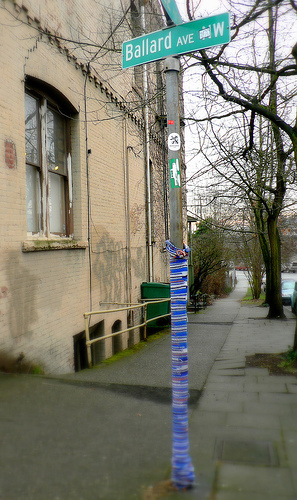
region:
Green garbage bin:
[141, 280, 169, 330]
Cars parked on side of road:
[282, 276, 295, 314]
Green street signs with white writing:
[120, 0, 232, 70]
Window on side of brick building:
[25, 72, 78, 245]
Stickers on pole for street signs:
[165, 119, 181, 192]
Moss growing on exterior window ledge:
[31, 237, 78, 247]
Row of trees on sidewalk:
[232, 108, 289, 322]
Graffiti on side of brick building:
[93, 231, 147, 303]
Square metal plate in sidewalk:
[213, 433, 280, 469]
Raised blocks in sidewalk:
[213, 355, 246, 380]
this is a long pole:
[163, 312, 219, 374]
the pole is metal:
[155, 208, 209, 312]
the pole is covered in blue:
[115, 288, 182, 356]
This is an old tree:
[218, 222, 280, 273]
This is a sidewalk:
[214, 322, 219, 417]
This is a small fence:
[71, 272, 163, 381]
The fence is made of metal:
[109, 310, 147, 403]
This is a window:
[26, 209, 49, 217]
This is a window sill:
[35, 212, 63, 238]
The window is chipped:
[37, 201, 61, 244]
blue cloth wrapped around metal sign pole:
[164, 238, 199, 489]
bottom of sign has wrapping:
[164, 235, 199, 483]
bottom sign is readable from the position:
[121, 11, 232, 67]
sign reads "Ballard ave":
[117, 9, 233, 62]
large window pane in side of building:
[22, 71, 81, 245]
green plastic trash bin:
[141, 280, 170, 330]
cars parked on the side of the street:
[277, 275, 296, 312]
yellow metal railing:
[74, 293, 179, 365]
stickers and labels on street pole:
[165, 116, 187, 195]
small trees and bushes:
[187, 214, 231, 312]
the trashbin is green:
[139, 272, 180, 333]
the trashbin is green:
[122, 268, 193, 353]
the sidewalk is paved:
[181, 287, 253, 405]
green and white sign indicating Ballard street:
[119, 12, 232, 68]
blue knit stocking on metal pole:
[164, 238, 199, 486]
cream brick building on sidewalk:
[0, 0, 190, 373]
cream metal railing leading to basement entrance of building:
[78, 290, 171, 359]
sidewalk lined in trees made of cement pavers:
[169, 284, 292, 486]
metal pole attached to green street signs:
[161, 55, 182, 246]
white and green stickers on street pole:
[169, 116, 183, 194]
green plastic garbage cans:
[140, 280, 172, 342]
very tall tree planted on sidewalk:
[185, 0, 296, 322]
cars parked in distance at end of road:
[230, 258, 296, 271]